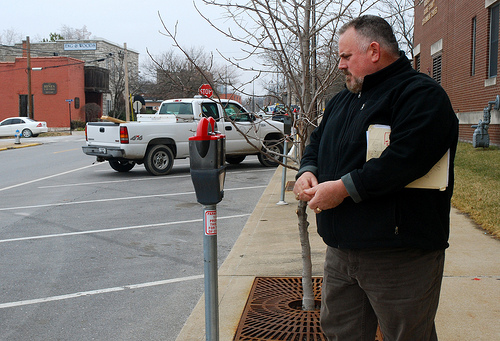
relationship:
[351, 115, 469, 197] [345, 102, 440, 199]
folder under arm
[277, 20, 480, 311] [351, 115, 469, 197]
man holding folder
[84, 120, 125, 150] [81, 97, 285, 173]
tailgate on truck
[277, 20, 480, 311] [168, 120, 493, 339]
man on sidewalk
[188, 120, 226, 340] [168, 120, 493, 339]
parking meter on sidewalk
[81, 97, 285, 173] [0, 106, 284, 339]
truck parked on street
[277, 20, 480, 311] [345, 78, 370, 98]
man with a beard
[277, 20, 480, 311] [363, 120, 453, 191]
man holding folder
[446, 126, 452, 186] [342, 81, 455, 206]
paper under arm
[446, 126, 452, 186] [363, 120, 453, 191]
paper in folder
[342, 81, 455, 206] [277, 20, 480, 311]
arm of man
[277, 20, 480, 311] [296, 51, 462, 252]
man wearing black jacket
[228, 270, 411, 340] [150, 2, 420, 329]
gate around tree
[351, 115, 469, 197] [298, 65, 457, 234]
folder under arm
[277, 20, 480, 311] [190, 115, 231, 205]
man pays meter